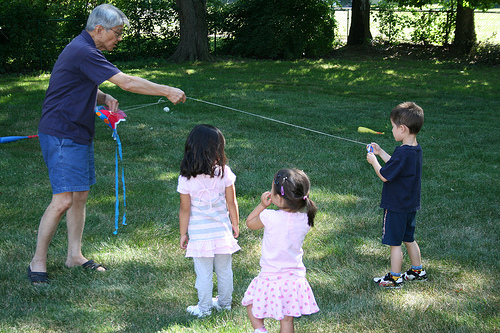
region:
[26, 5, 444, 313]
older man playing with three kids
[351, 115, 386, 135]
toy bat in the grass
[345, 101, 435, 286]
little boy holding string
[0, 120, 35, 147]
blue toy bat with red handle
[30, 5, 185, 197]
man holding kite and string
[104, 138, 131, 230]
tail of a kite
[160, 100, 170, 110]
baseball on the grass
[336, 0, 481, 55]
two tree trunks in the shade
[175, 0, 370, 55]
thick bush between two trees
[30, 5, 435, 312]
adult and kids trying to fly a kite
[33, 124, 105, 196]
the man is wearing shorts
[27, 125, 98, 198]
the man's shorts are blue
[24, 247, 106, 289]
the man is wearing black shoes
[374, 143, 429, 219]
the boy is wearing a t-shirt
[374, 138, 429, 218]
the boy's t-shirt is blue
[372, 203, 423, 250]
the boy is wearing shorts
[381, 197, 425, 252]
the boy's shorts are blue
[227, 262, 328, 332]
the little girl is wearing a skirt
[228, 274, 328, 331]
the girl's skirt is polka dot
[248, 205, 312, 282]
the girl is wearing a white t-shirt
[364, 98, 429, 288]
a little boy standing in the grass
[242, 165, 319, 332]
a little girl wearing a skirt and a pony tail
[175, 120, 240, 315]
a little girl wearing blue and white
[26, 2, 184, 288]
an old man with gray hair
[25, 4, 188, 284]
an old man wearing glasses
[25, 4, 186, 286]
an old man wearing denim shorts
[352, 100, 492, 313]
a little boy with sunlight on his head and around his feet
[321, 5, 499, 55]
a chain link fence behind the trees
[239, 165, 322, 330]
a little girl with purple hair bows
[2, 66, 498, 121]
shadows on the ground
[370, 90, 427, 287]
Young boy wearing a blue shirt and blue shorts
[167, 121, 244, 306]
Little girl with black hair wearing a shirt with blue stripes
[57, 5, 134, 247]
Man wearing a blue shirt and short blue shorts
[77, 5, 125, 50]
Man with glasses and gray hair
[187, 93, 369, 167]
Thin light blue string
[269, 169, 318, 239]
Little girl with brown hair tied with a hair tie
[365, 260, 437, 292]
Black and white sneakers with a colorful pattern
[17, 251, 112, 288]
Black sandals on a man's feet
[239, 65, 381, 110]
field of dark green grass bathed in shadow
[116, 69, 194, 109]
Man's bare forearm holding a string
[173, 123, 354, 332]
two little girls standing on the grass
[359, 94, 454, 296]
little boy standing on the grass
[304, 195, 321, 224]
hair pulled back into a ponytail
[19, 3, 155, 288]
older man holding a kite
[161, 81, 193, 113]
hamd on the string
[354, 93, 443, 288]
little boy holding the kite string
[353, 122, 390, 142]
yellow bat laying in the grass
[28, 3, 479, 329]
man playing with three kids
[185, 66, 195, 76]
light shining on the ground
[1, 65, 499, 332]
green grass on the ground